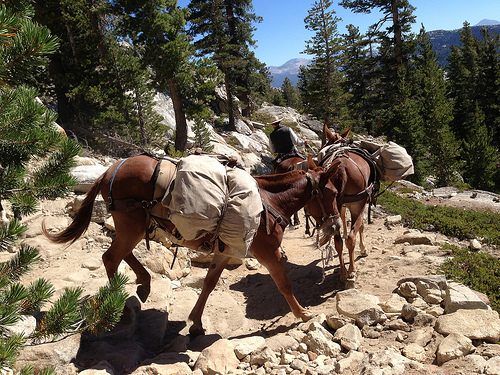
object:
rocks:
[88, 269, 500, 375]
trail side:
[2, 184, 499, 374]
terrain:
[0, 103, 500, 373]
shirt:
[268, 124, 306, 153]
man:
[266, 115, 309, 163]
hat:
[266, 115, 284, 125]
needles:
[0, 273, 142, 374]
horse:
[40, 124, 378, 336]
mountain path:
[0, 141, 499, 374]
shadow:
[64, 295, 223, 375]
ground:
[0, 272, 499, 375]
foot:
[135, 279, 150, 304]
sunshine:
[282, 60, 306, 72]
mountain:
[266, 53, 311, 93]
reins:
[310, 211, 343, 286]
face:
[310, 178, 344, 234]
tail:
[39, 169, 102, 256]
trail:
[0, 156, 499, 374]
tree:
[0, 0, 272, 374]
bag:
[161, 154, 265, 259]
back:
[119, 151, 264, 198]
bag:
[360, 136, 415, 182]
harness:
[305, 171, 341, 285]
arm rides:
[266, 115, 308, 171]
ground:
[18, 123, 197, 176]